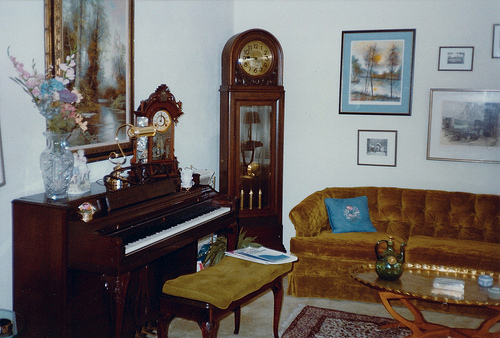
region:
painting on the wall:
[334, 15, 427, 134]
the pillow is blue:
[309, 180, 394, 249]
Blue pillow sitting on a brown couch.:
[320, 190, 380, 237]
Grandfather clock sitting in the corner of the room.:
[215, 24, 292, 190]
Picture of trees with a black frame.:
[337, 26, 419, 117]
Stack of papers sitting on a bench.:
[223, 238, 300, 272]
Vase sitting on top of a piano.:
[31, 126, 78, 202]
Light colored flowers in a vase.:
[5, 41, 95, 140]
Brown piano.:
[7, 159, 243, 336]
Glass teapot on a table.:
[371, 234, 410, 281]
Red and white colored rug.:
[273, 295, 387, 337]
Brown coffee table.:
[352, 260, 499, 330]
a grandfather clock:
[216, 24, 290, 247]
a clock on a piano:
[128, 83, 188, 175]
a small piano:
[10, 179, 264, 320]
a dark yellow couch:
[285, 183, 497, 312]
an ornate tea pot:
[369, 230, 412, 285]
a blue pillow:
[322, 191, 376, 233]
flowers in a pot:
[6, 43, 88, 200]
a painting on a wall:
[336, 24, 418, 123]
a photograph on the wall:
[435, 44, 479, 74]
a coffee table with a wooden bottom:
[349, 255, 499, 336]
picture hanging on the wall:
[339, 26, 414, 118]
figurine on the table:
[368, 238, 409, 280]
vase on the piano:
[41, 127, 71, 203]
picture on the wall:
[353, 128, 398, 165]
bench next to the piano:
[165, 245, 322, 335]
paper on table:
[427, 272, 474, 296]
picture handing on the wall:
[426, 85, 498, 166]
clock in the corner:
[218, 29, 298, 236]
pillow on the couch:
[328, 195, 372, 233]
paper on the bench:
[223, 239, 294, 271]